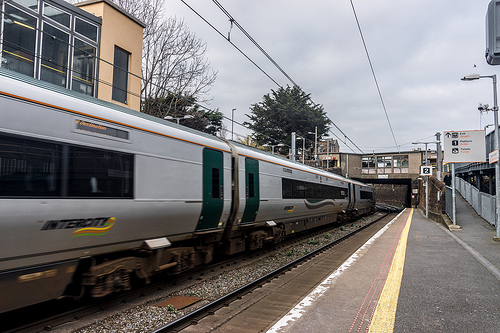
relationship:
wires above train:
[0, 0, 402, 158] [1, 66, 378, 314]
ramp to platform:
[446, 181, 498, 269] [392, 208, 498, 332]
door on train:
[197, 147, 224, 230] [1, 66, 378, 314]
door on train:
[243, 156, 263, 223] [1, 66, 378, 314]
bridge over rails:
[308, 150, 446, 207] [2, 202, 407, 332]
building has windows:
[1, 0, 145, 113] [0, 0, 98, 97]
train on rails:
[1, 66, 378, 314] [2, 202, 407, 332]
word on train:
[38, 217, 111, 232] [1, 66, 378, 314]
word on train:
[283, 204, 298, 212] [1, 66, 378, 314]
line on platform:
[367, 207, 417, 332] [392, 208, 498, 332]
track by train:
[158, 207, 409, 332] [1, 66, 378, 314]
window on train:
[0, 132, 135, 199] [1, 66, 378, 314]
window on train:
[281, 177, 352, 203] [1, 66, 378, 314]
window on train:
[360, 190, 377, 202] [1, 66, 378, 314]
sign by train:
[443, 129, 487, 164] [1, 66, 378, 314]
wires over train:
[0, 0, 402, 158] [1, 66, 378, 314]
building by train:
[1, 0, 145, 113] [1, 66, 378, 314]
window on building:
[1, 1, 37, 77] [1, 0, 145, 113]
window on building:
[39, 1, 72, 87] [1, 0, 145, 113]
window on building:
[69, 12, 103, 97] [1, 0, 145, 113]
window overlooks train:
[1, 1, 37, 77] [1, 66, 378, 314]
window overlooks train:
[39, 1, 72, 87] [1, 66, 378, 314]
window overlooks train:
[69, 12, 103, 97] [1, 66, 378, 314]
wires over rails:
[0, 0, 402, 158] [2, 202, 407, 332]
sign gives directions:
[443, 129, 487, 164] [443, 129, 475, 155]